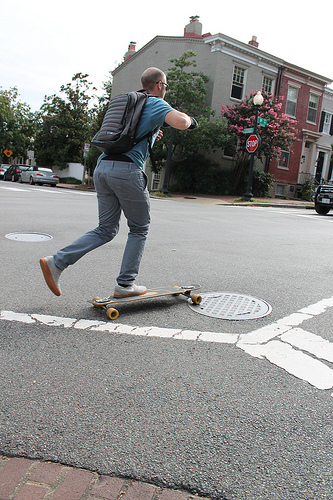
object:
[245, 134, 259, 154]
sign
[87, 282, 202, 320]
skate board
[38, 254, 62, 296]
shoe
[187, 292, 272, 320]
cover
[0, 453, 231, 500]
bricks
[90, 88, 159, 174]
back pack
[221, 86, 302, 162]
flowers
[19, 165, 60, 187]
car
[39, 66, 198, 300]
man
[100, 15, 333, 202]
building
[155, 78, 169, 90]
glasses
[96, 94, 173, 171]
shirt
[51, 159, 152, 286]
pants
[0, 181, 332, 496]
street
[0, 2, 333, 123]
sky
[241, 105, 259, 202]
pole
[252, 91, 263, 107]
light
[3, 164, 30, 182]
car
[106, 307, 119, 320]
wheel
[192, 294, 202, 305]
wheel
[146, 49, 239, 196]
trees